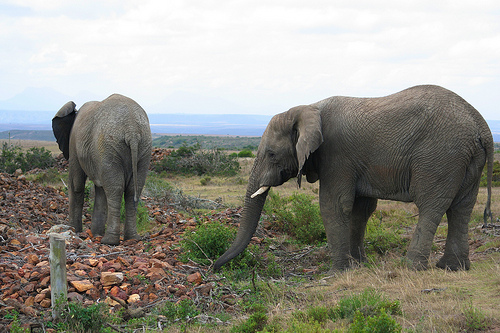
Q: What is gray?
A: Elephants.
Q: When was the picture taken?
A: Daytime.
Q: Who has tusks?
A: The elephants.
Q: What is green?
A: Grass.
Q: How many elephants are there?
A: Two.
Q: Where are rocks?
A: On the ground.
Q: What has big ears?
A: Two elephants.